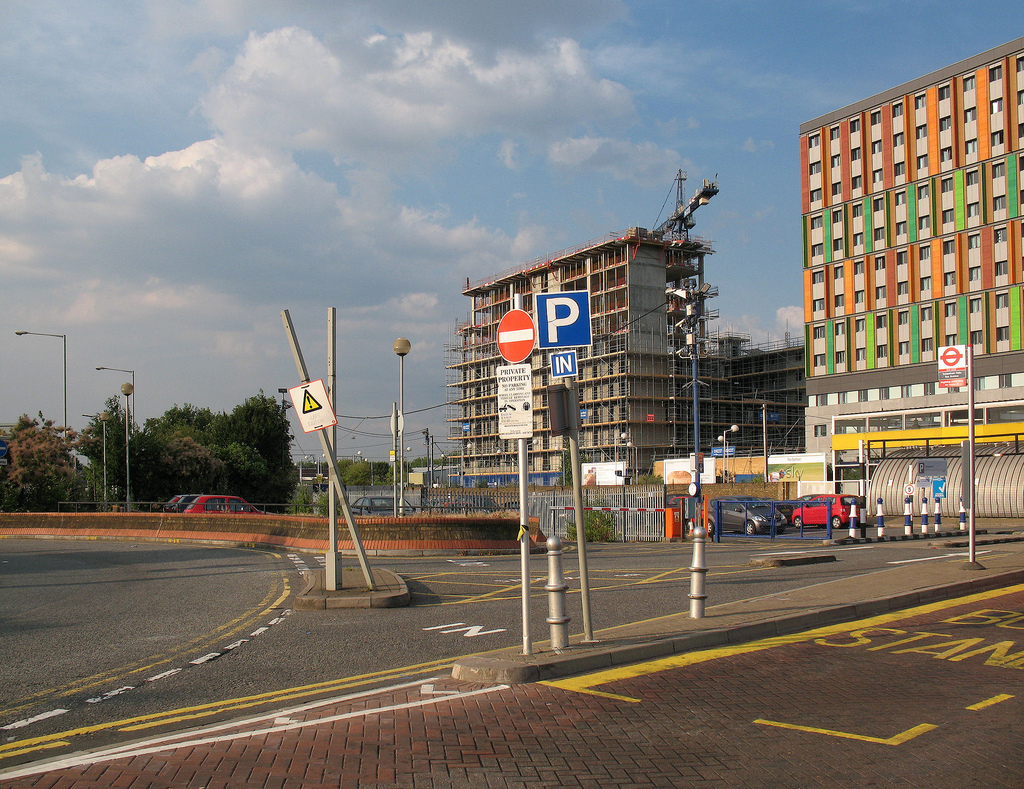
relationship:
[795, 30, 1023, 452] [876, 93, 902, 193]
apartment has trim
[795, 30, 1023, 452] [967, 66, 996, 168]
apartment has trim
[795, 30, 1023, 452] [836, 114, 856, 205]
apartment has trim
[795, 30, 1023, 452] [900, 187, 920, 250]
apartment has trim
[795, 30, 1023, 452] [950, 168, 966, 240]
apartment has trim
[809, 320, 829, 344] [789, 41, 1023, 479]
window on a building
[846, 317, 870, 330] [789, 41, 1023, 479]
window on a building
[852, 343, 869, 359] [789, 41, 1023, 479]
window on a building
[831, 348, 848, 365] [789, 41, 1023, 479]
window on a building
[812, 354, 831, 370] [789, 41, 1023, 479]
window on a building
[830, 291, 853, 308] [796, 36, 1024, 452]
window on a apartment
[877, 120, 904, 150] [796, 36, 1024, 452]
window on a apartment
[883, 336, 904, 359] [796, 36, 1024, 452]
window on a apartment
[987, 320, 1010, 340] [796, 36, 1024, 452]
window on a apartment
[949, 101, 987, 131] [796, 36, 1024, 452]
window on a apartment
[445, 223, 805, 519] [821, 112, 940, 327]
building on building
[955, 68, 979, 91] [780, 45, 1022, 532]
window on building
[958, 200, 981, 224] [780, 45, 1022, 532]
window on building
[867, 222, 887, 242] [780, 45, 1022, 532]
window on building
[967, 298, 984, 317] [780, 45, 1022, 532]
window on building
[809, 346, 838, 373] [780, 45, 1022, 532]
window on building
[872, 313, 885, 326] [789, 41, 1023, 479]
window on building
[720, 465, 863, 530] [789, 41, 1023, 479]
cars parked in front of building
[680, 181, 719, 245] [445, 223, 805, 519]
sky crane over building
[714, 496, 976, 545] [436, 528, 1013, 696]
line over median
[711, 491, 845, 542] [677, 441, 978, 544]
gate in front of parking area